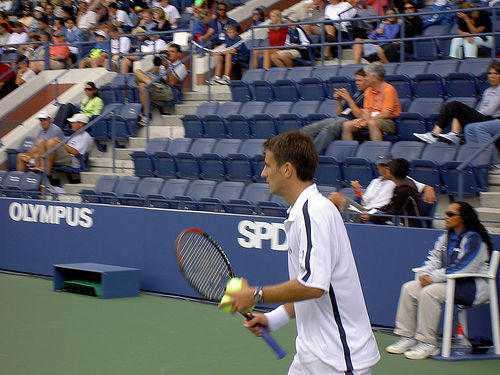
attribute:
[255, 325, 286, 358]
handle — blue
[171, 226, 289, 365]
racket — black, red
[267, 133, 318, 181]
hair — brown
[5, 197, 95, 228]
writing — white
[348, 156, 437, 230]
people — sitting, talking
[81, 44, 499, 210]
seats — blue, empty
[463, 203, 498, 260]
hair — black, long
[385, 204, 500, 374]
person — sitting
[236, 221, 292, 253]
letters — white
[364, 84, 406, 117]
shirt — orange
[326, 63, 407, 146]
people — sitting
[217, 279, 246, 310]
balls — tennis, green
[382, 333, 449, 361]
sneakers — white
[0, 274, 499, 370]
court — green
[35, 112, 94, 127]
hats — white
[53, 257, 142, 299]
stand — small, blue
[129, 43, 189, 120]
man — sitting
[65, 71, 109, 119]
person — alone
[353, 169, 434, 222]
shirt — white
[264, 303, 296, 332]
band — white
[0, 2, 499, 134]
people — sitting, watching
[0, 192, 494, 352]
wall — blue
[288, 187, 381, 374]
shirt — white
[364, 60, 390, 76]
hair — grey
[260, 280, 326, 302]
skin — light